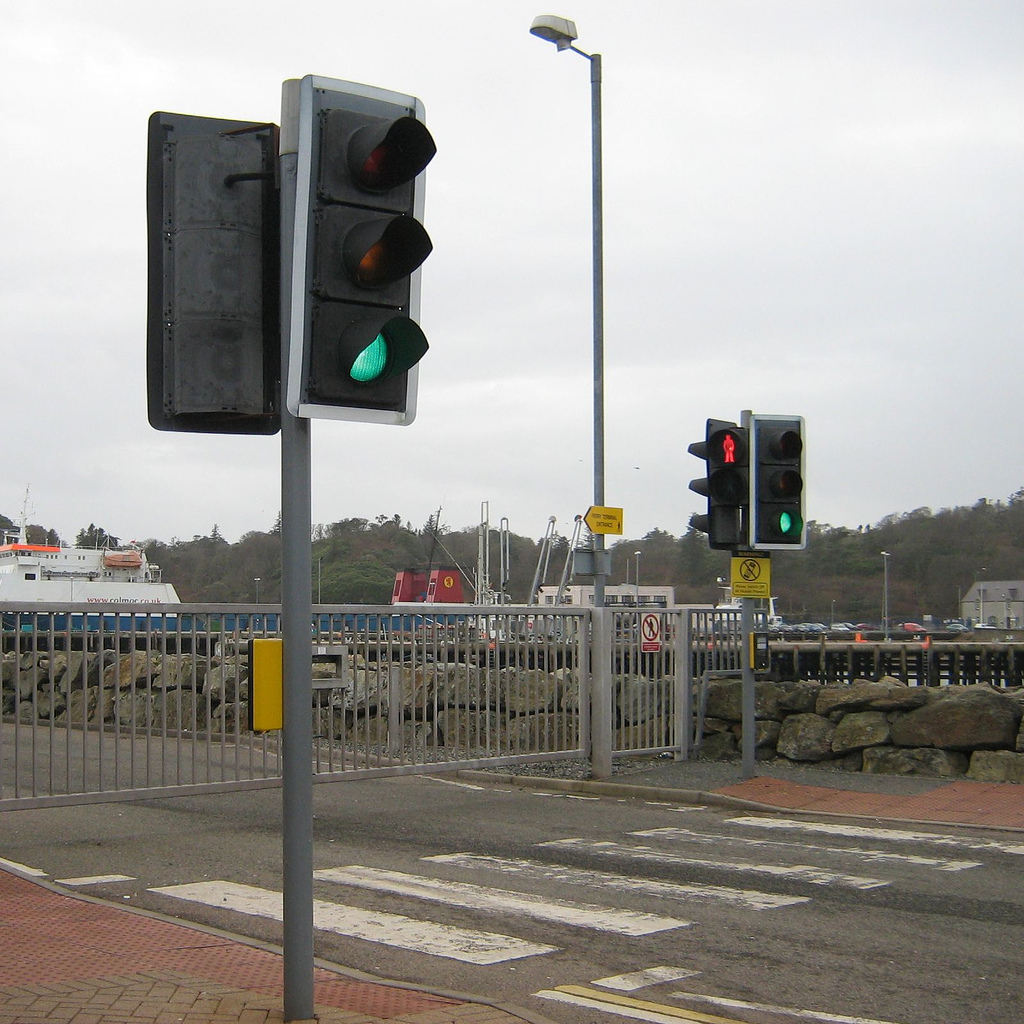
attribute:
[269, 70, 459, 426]
signal — traffic signal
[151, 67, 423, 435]
signal — electric, traffic signal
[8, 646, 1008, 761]
wall — long, stone wall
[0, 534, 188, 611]
ship — large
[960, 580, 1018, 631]
building — gray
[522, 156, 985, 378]
cloud — covered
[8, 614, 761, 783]
rails — metal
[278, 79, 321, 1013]
pole — metal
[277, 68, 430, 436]
light — green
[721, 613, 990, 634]
cars — parked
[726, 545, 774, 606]
sign — yellow, black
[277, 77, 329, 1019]
pole — grey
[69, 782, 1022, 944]
street — grey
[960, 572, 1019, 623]
house — beige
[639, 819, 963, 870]
line — long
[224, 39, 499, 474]
traffic — electric